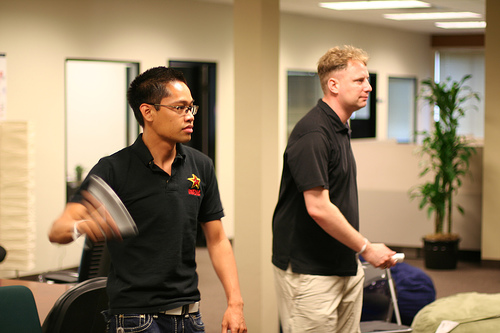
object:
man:
[47, 65, 249, 333]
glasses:
[144, 103, 199, 115]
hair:
[125, 66, 189, 128]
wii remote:
[86, 174, 138, 237]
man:
[270, 44, 396, 332]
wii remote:
[390, 253, 405, 264]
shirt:
[68, 131, 227, 317]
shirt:
[270, 96, 360, 277]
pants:
[274, 255, 366, 332]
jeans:
[95, 300, 206, 333]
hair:
[316, 44, 369, 97]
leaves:
[456, 202, 466, 217]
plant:
[411, 72, 485, 274]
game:
[79, 173, 139, 246]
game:
[362, 252, 406, 265]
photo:
[0, 0, 499, 333]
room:
[1, 1, 496, 331]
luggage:
[388, 262, 438, 326]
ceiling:
[280, 0, 484, 36]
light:
[169, 80, 186, 95]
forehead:
[160, 77, 194, 101]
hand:
[75, 189, 123, 246]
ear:
[327, 78, 338, 95]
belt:
[159, 302, 201, 316]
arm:
[286, 136, 370, 256]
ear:
[139, 103, 155, 122]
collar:
[133, 132, 187, 168]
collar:
[317, 98, 353, 137]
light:
[317, 0, 432, 11]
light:
[382, 11, 481, 20]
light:
[434, 21, 486, 29]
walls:
[0, 1, 500, 273]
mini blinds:
[438, 47, 483, 141]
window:
[432, 48, 486, 147]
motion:
[73, 187, 122, 248]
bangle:
[71, 222, 81, 241]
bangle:
[357, 237, 368, 258]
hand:
[364, 243, 396, 271]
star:
[187, 173, 201, 189]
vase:
[421, 235, 462, 271]